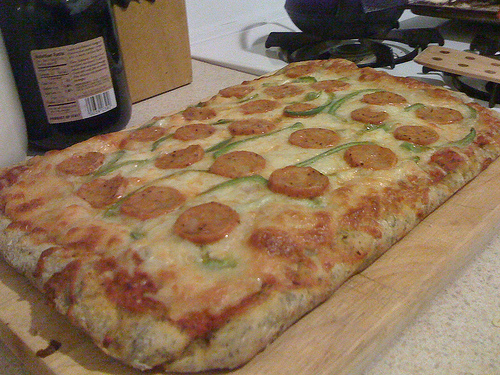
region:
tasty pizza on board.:
[18, 26, 490, 363]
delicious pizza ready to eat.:
[15, 28, 475, 360]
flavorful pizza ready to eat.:
[11, 36, 483, 356]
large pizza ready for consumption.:
[6, 46, 478, 353]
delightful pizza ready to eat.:
[6, 35, 481, 360]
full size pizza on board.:
[8, 25, 471, 360]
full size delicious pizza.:
[1, 49, 481, 361]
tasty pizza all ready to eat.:
[5, 17, 475, 359]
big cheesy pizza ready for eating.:
[5, 24, 479, 356]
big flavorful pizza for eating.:
[11, 25, 481, 360]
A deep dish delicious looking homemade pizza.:
[0, 55, 495, 370]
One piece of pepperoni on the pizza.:
[170, 200, 241, 245]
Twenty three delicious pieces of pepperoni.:
[50, 60, 460, 240]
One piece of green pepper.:
[190, 172, 266, 197]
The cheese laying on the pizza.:
[265, 138, 285, 159]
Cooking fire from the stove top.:
[263, 25, 444, 58]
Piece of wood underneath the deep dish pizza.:
[0, 153, 498, 372]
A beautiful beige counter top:
[0, 50, 497, 370]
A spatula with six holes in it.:
[410, 40, 495, 76]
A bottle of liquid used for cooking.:
[0, 0, 136, 150]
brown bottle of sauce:
[23, 19, 150, 124]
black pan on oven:
[288, 6, 408, 38]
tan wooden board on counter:
[344, 190, 489, 372]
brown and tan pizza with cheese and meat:
[31, 263, 259, 363]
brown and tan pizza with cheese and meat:
[18, 180, 208, 297]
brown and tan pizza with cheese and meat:
[141, 111, 288, 188]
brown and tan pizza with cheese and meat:
[268, 154, 435, 228]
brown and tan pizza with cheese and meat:
[263, 63, 376, 146]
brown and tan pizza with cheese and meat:
[363, 86, 490, 188]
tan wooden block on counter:
[132, 32, 223, 88]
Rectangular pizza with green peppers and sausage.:
[4, 50, 495, 365]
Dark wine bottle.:
[2, 0, 147, 144]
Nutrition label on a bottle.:
[21, 28, 130, 135]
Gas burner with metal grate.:
[251, 22, 438, 71]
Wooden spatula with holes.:
[392, 39, 498, 84]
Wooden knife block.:
[95, 0, 206, 92]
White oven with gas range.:
[182, 0, 498, 127]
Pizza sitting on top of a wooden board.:
[15, 57, 482, 371]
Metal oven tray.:
[406, 0, 498, 30]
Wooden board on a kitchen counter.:
[339, 227, 495, 372]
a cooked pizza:
[5, 51, 497, 371]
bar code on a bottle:
[72, 80, 119, 118]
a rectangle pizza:
[5, 58, 499, 347]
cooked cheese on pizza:
[17, 157, 204, 330]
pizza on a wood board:
[6, 76, 498, 334]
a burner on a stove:
[255, 13, 447, 70]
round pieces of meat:
[59, 147, 244, 249]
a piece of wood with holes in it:
[411, 39, 498, 81]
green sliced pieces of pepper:
[190, 116, 371, 188]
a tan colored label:
[8, 9, 150, 131]